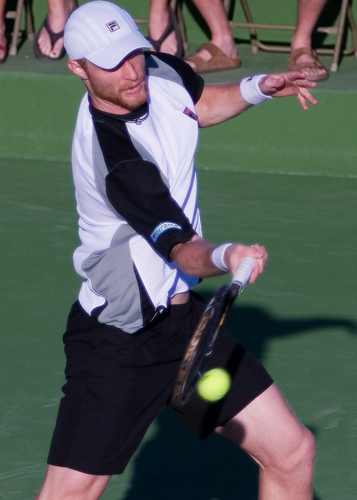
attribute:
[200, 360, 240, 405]
ball — green, small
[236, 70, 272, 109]
band — white, big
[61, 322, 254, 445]
shorts — black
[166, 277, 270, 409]
racket — black, big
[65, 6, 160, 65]
hat — white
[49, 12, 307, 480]
adult — white, big, focused, old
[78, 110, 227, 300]
shirt — white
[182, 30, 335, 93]
shoes — big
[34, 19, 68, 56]
shoes — big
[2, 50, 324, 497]
court — big